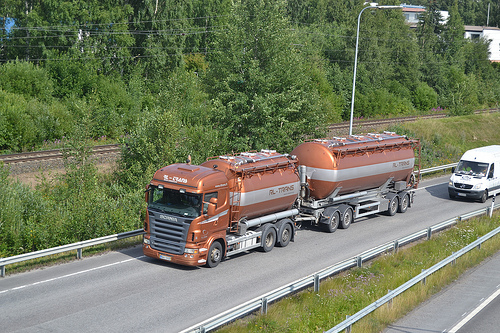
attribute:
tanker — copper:
[139, 128, 420, 270]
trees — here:
[1, 7, 498, 117]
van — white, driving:
[447, 139, 499, 204]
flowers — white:
[310, 288, 376, 306]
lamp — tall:
[348, 3, 403, 136]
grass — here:
[310, 291, 339, 322]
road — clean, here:
[200, 163, 499, 332]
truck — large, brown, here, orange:
[144, 130, 425, 268]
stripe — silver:
[228, 156, 413, 207]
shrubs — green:
[1, 100, 93, 146]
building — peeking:
[365, 6, 498, 68]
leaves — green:
[262, 66, 318, 124]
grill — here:
[146, 212, 191, 255]